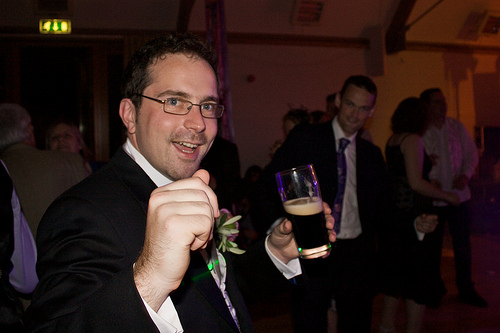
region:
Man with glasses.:
[99, 45, 259, 191]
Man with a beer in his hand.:
[259, 148, 398, 300]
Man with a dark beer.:
[266, 132, 370, 289]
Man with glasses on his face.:
[113, 57, 249, 156]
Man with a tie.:
[94, 123, 281, 331]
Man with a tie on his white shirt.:
[308, 50, 392, 254]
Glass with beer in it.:
[265, 158, 393, 288]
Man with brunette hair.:
[108, 28, 251, 128]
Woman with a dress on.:
[378, 68, 455, 325]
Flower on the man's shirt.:
[191, 195, 281, 280]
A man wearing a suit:
[24, 30, 304, 330]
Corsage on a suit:
[190, 204, 248, 285]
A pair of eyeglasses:
[124, 81, 228, 122]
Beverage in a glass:
[269, 160, 335, 264]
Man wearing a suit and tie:
[262, 69, 441, 329]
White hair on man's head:
[2, 100, 41, 154]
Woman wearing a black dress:
[380, 92, 463, 331]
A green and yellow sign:
[33, 14, 75, 40]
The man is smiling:
[110, 30, 226, 188]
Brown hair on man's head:
[107, 29, 229, 190]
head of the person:
[106, 27, 253, 170]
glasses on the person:
[141, 85, 235, 132]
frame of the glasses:
[150, 89, 197, 126]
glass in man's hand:
[271, 150, 345, 266]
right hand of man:
[125, 158, 244, 262]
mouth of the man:
[161, 125, 208, 173]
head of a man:
[328, 68, 390, 148]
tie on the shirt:
[315, 127, 366, 192]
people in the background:
[380, 86, 474, 176]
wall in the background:
[268, 55, 328, 91]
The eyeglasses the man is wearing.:
[138, 91, 223, 127]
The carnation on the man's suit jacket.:
[211, 204, 243, 257]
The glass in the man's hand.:
[280, 167, 335, 255]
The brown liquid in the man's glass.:
[282, 205, 328, 245]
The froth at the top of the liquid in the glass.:
[281, 195, 322, 212]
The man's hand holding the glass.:
[273, 203, 344, 260]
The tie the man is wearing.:
[337, 137, 351, 230]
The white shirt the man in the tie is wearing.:
[326, 117, 373, 242]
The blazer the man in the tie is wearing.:
[255, 125, 413, 272]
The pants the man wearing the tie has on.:
[295, 243, 364, 330]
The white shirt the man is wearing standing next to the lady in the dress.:
[419, 117, 476, 200]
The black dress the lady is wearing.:
[381, 127, 421, 299]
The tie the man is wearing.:
[326, 140, 348, 232]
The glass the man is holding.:
[273, 162, 338, 257]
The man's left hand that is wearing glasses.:
[128, 178, 223, 302]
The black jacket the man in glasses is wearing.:
[40, 153, 258, 332]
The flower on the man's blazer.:
[213, 190, 247, 269]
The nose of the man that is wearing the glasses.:
[185, 113, 207, 136]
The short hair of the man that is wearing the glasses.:
[120, 38, 223, 103]